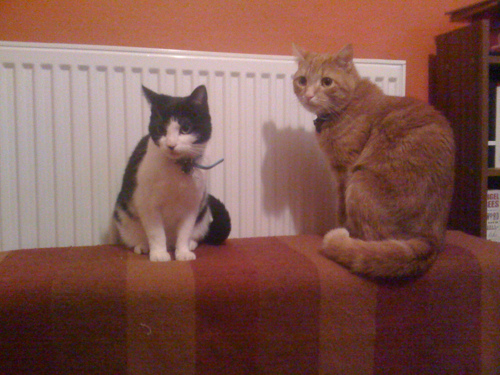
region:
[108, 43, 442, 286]
two cats sitting on ottoman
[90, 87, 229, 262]
black and white cat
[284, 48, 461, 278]
orange cat sitting on ottoman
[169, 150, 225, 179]
collar of white and black cat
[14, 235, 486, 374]
striped ottoman cats are sitting on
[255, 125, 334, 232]
shadow on wall from orange cat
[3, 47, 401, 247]
white paneling on wall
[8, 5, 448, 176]
orange wall behind cats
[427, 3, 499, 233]
bookshelf beside the ottoman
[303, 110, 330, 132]
collar of orange cat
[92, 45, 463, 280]
two cats sitting together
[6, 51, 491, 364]
cats sitting on striped ottoman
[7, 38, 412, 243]
white panel on wall behind ottoman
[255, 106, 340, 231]
cat's shadow on white panel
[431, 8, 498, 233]
wood bookcase beside orange cat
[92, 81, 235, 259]
black and white cat wearing collar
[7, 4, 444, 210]
orange wall behind two cats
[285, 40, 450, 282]
orange cat wearing collar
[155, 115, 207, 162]
white markings on black and white cat's face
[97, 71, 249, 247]
a black and white cat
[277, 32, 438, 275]
an orange and striped cat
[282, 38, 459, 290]
orange cat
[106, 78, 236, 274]
black and white cat sitting on orange bench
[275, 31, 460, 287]
orange cat sitting on orange bench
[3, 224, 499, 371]
orange bench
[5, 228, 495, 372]
orange bench with two cats on it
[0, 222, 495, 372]
light and dark orange bench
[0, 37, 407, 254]
white back of bench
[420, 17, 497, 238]
wooden book shelf sitting beside orange bench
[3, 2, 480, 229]
orange wall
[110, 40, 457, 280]
two cats sitting on the chair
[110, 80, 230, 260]
one grey and white cat on chair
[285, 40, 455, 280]
one brown and tan cat sitting on the chair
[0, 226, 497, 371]
striped color seat of chair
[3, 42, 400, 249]
white back rest of chair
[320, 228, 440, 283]
tail of brown and tan cat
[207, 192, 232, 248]
tail of black and white cat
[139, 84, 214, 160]
head of black and white cat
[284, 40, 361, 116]
head of tan and brown cat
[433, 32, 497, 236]
side cabinate door next to chair